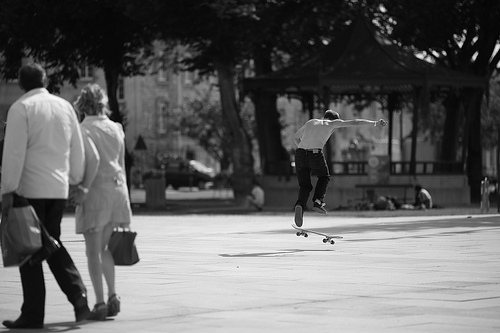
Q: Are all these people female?
A: No, they are both male and female.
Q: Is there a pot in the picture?
A: No, there are no pots.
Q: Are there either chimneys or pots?
A: No, there are no pots or chimneys.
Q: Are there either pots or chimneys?
A: No, there are no pots or chimneys.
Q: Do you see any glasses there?
A: No, there are no glasses.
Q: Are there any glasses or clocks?
A: No, there are no glasses or clocks.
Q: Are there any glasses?
A: No, there are no glasses.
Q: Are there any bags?
A: Yes, there is a bag.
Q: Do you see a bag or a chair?
A: Yes, there is a bag.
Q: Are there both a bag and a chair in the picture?
A: No, there is a bag but no chairs.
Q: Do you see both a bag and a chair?
A: No, there is a bag but no chairs.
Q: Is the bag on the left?
A: Yes, the bag is on the left of the image.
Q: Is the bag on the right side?
A: No, the bag is on the left of the image.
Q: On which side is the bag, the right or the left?
A: The bag is on the left of the image.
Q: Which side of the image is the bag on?
A: The bag is on the left of the image.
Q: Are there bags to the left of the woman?
A: Yes, there is a bag to the left of the woman.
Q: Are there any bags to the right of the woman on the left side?
A: No, the bag is to the left of the woman.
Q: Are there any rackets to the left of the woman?
A: No, there is a bag to the left of the woman.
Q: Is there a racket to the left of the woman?
A: No, there is a bag to the left of the woman.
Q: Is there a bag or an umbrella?
A: Yes, there is a bag.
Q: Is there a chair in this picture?
A: No, there are no chairs.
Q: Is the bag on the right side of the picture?
A: No, the bag is on the left of the image.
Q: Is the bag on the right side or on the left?
A: The bag is on the left of the image.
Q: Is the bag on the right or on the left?
A: The bag is on the left of the image.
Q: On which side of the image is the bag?
A: The bag is on the left of the image.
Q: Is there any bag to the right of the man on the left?
A: Yes, there is a bag to the right of the man.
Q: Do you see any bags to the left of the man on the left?
A: No, the bag is to the right of the man.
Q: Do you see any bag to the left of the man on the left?
A: No, the bag is to the right of the man.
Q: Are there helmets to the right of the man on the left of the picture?
A: No, there is a bag to the right of the man.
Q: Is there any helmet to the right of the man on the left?
A: No, there is a bag to the right of the man.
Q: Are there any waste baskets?
A: No, there are no waste baskets.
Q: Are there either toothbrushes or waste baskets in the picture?
A: No, there are no waste baskets or toothbrushes.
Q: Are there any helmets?
A: No, there are no helmets.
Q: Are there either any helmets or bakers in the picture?
A: No, there are no helmets or bakers.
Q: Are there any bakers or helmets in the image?
A: No, there are no helmets or bakers.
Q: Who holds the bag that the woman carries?
A: The man holds the bag.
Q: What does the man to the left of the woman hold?
A: The man holds the bag.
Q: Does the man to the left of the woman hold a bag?
A: Yes, the man holds a bag.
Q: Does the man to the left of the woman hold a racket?
A: No, the man holds a bag.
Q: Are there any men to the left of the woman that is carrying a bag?
A: Yes, there is a man to the left of the woman.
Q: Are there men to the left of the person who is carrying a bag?
A: Yes, there is a man to the left of the woman.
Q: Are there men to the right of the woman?
A: No, the man is to the left of the woman.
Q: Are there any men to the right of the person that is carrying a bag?
A: No, the man is to the left of the woman.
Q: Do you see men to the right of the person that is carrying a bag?
A: No, the man is to the left of the woman.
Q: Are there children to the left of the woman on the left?
A: No, there is a man to the left of the woman.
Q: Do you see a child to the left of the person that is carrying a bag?
A: No, there is a man to the left of the woman.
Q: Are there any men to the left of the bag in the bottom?
A: Yes, there is a man to the left of the bag.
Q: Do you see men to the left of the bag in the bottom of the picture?
A: Yes, there is a man to the left of the bag.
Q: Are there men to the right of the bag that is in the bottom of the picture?
A: No, the man is to the left of the bag.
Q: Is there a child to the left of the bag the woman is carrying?
A: No, there is a man to the left of the bag.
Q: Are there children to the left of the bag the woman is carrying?
A: No, there is a man to the left of the bag.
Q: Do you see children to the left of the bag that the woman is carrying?
A: No, there is a man to the left of the bag.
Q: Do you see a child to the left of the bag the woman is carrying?
A: No, there is a man to the left of the bag.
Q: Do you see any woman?
A: Yes, there is a woman.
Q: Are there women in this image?
A: Yes, there is a woman.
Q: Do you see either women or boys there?
A: Yes, there is a woman.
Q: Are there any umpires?
A: No, there are no umpires.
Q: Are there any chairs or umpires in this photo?
A: No, there are no umpires or chairs.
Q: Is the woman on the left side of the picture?
A: Yes, the woman is on the left of the image.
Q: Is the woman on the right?
A: No, the woman is on the left of the image.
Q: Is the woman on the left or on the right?
A: The woman is on the left of the image.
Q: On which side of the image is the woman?
A: The woman is on the left of the image.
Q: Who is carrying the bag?
A: The woman is carrying the bag.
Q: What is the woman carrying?
A: The woman is carrying a bag.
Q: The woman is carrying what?
A: The woman is carrying a bag.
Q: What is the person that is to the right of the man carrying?
A: The woman is carrying a bag.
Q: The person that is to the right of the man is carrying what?
A: The woman is carrying a bag.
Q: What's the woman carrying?
A: The woman is carrying a bag.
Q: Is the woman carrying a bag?
A: Yes, the woman is carrying a bag.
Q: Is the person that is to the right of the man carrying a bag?
A: Yes, the woman is carrying a bag.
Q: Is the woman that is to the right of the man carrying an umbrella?
A: No, the woman is carrying a bag.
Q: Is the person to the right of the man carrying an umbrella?
A: No, the woman is carrying a bag.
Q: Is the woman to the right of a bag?
A: Yes, the woman is to the right of a bag.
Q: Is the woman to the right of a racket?
A: No, the woman is to the right of a bag.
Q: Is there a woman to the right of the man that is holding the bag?
A: Yes, there is a woman to the right of the man.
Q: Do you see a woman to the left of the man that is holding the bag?
A: No, the woman is to the right of the man.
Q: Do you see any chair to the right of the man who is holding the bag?
A: No, there is a woman to the right of the man.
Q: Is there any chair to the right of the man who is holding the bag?
A: No, there is a woman to the right of the man.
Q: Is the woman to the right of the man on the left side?
A: Yes, the woman is to the right of the man.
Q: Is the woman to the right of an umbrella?
A: No, the woman is to the right of the man.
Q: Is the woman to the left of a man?
A: No, the woman is to the right of a man.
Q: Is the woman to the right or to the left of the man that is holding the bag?
A: The woman is to the right of the man.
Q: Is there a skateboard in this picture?
A: Yes, there is a skateboard.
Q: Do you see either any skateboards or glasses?
A: Yes, there is a skateboard.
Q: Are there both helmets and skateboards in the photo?
A: No, there is a skateboard but no helmets.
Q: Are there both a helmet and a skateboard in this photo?
A: No, there is a skateboard but no helmets.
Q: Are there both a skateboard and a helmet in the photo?
A: No, there is a skateboard but no helmets.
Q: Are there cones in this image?
A: No, there are no cones.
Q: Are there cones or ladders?
A: No, there are no cones or ladders.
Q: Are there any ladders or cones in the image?
A: No, there are no cones or ladders.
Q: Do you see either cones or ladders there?
A: No, there are no cones or ladders.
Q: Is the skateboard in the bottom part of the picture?
A: Yes, the skateboard is in the bottom of the image.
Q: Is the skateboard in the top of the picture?
A: No, the skateboard is in the bottom of the image.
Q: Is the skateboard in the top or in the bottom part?
A: The skateboard is in the bottom of the image.